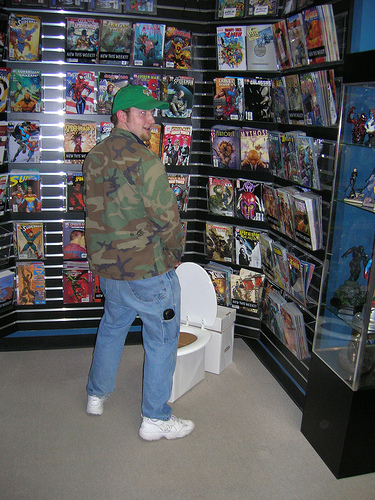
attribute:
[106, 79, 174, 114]
cap — green, clean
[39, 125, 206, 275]
jacket — camouflage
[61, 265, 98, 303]
spiderman — superhero, Marvel's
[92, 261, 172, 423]
jeans — blue, denim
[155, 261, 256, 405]
toilet — small, white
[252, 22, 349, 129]
books — comic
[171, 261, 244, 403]
toilet — fake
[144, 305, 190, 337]
case — black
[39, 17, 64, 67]
shelf — metal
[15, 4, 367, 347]
wall — black, white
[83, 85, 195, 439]
man — standing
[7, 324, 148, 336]
line — blue